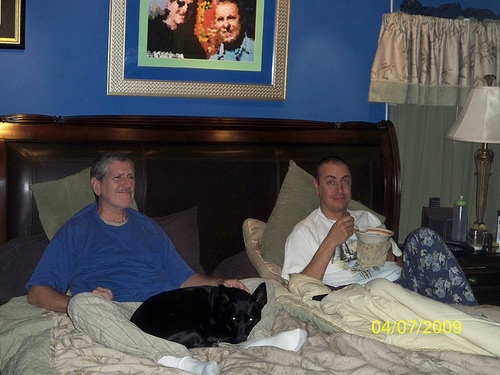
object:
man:
[26, 153, 309, 373]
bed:
[0, 113, 496, 370]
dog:
[130, 280, 268, 349]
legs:
[61, 284, 225, 375]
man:
[278, 158, 485, 309]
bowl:
[356, 226, 394, 247]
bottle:
[450, 194, 472, 245]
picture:
[103, 1, 291, 100]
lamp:
[443, 85, 500, 252]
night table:
[386, 237, 500, 309]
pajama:
[391, 226, 476, 303]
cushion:
[253, 160, 390, 270]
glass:
[466, 230, 483, 253]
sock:
[156, 355, 216, 373]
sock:
[244, 326, 308, 356]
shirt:
[280, 208, 413, 285]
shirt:
[24, 202, 197, 310]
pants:
[65, 276, 275, 363]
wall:
[0, 1, 499, 120]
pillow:
[241, 215, 288, 284]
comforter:
[11, 273, 500, 374]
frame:
[102, 0, 290, 102]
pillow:
[28, 167, 141, 246]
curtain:
[366, 12, 500, 108]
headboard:
[0, 111, 404, 295]